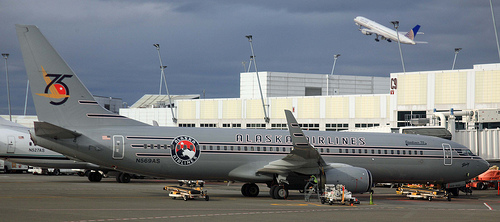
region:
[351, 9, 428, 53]
A plane is taking off.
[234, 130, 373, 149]
The plane says Alaska Airlines.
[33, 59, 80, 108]
The tail of the plane says 75.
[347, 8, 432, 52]
The plane is white.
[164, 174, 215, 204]
Vehicles are near the planes.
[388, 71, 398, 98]
The building has letters and numbers on it.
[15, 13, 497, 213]
this is a plane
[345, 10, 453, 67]
this is a plane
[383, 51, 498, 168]
this is a building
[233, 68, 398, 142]
this is a building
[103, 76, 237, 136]
this is a building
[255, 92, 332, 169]
a wing of a plane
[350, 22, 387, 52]
a wing of a plane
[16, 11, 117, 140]
a wing of a plane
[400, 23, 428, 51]
a wing of a plane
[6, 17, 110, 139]
the tail of a plane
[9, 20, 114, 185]
Tail on a plane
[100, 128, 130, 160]
Door on a gray plane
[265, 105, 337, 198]
Wing on a gray plane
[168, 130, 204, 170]
Red and blue symbol on a gray plane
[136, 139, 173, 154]
Windows on a gray plane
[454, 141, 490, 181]
Nose on a gray plane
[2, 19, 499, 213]
Gray plane at an airport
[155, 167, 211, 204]
Trailer by a plane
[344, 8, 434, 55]
White plane in the air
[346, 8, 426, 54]
White plane flying in the air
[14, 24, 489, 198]
jet is large and grey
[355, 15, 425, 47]
white and blue airplane is flying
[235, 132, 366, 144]
plane says alaska airline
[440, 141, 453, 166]
plane has a gray door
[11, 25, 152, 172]
plane has a gray tail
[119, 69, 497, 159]
large airport is white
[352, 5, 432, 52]
plane departing the airport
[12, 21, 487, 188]
dark grey passenger jet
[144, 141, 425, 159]
windows along the passenger seating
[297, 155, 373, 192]
engine mounted under the wing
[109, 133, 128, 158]
rear access door to the interior of the plane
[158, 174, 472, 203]
Lifters and loaders surround the aircraft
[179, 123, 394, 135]
windows on the building with small panes of glass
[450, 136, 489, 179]
cockpit of the plane just above the nose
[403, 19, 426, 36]
blue and white tail on plane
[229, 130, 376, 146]
name of the airline company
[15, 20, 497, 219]
this is a plane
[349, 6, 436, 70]
this plane is white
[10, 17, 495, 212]
this plane is gray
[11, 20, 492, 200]
Plane is Alaska airline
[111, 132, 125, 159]
Airplane door is close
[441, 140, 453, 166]
Rectangular airplane door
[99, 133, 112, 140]
US flag printed on the plane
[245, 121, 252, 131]
a window on a building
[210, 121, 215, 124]
a window on a building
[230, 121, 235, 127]
a window on a building